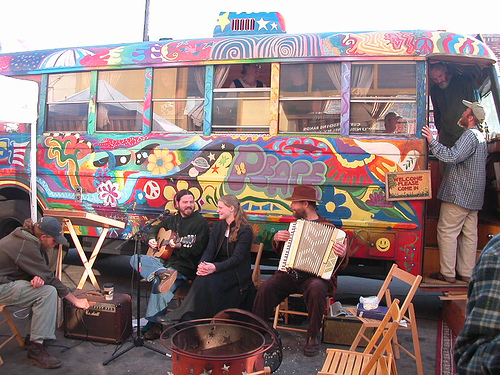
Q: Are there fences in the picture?
A: No, there are no fences.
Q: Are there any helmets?
A: No, there are no helmets.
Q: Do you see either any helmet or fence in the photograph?
A: No, there are no helmets or fences.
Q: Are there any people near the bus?
A: Yes, there is a person near the bus.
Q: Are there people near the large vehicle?
A: Yes, there is a person near the bus.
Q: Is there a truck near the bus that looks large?
A: No, there is a person near the bus.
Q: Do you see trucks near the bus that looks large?
A: No, there is a person near the bus.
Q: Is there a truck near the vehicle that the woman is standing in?
A: No, there is a person near the bus.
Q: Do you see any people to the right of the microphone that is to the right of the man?
A: Yes, there is a person to the right of the microphone.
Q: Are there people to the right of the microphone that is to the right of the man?
A: Yes, there is a person to the right of the microphone.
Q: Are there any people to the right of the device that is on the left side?
A: Yes, there is a person to the right of the microphone.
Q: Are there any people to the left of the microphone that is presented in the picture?
A: No, the person is to the right of the microphone.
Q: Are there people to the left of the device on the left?
A: No, the person is to the right of the microphone.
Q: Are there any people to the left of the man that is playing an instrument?
A: Yes, there is a person to the left of the man.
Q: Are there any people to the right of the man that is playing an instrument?
A: No, the person is to the left of the man.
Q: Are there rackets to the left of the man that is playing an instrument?
A: No, there is a person to the left of the man.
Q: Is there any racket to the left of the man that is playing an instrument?
A: No, there is a person to the left of the man.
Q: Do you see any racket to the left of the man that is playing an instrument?
A: No, there is a person to the left of the man.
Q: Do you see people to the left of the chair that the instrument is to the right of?
A: Yes, there is a person to the left of the chair.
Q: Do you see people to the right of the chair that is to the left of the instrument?
A: No, the person is to the left of the chair.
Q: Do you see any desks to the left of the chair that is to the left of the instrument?
A: No, there is a person to the left of the chair.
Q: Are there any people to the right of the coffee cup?
A: Yes, there is a person to the right of the coffee cup.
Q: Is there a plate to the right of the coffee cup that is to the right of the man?
A: No, there is a person to the right of the coffee cup.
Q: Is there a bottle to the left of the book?
A: No, there is a person to the left of the book.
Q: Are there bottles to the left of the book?
A: No, there is a person to the left of the book.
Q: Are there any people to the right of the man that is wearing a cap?
A: Yes, there is a person to the right of the man.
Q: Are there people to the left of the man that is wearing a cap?
A: No, the person is to the right of the man.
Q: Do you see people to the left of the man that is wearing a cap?
A: No, the person is to the right of the man.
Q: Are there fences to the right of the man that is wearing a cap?
A: No, there is a person to the right of the man.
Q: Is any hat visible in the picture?
A: Yes, there is a hat.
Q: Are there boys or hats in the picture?
A: Yes, there is a hat.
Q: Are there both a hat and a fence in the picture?
A: No, there is a hat but no fences.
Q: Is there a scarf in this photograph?
A: No, there are no scarves.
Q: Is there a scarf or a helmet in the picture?
A: No, there are no scarves or helmets.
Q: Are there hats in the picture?
A: Yes, there is a hat.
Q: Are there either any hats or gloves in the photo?
A: Yes, there is a hat.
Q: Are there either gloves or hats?
A: Yes, there is a hat.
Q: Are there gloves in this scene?
A: No, there are no gloves.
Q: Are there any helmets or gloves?
A: No, there are no gloves or helmets.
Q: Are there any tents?
A: No, there are no tents.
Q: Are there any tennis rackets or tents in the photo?
A: No, there are no tents or tennis rackets.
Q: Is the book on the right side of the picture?
A: Yes, the book is on the right of the image.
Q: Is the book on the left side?
A: No, the book is on the right of the image.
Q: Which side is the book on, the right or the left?
A: The book is on the right of the image.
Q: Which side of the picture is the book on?
A: The book is on the right of the image.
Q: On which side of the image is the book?
A: The book is on the right of the image.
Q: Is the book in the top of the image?
A: No, the book is in the bottom of the image.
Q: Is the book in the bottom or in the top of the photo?
A: The book is in the bottom of the image.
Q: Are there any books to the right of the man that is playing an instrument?
A: Yes, there is a book to the right of the man.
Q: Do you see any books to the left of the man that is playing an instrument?
A: No, the book is to the right of the man.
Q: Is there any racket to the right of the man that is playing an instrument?
A: No, there is a book to the right of the man.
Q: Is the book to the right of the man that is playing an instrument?
A: Yes, the book is to the right of the man.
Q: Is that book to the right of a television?
A: No, the book is to the right of the man.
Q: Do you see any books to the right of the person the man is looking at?
A: Yes, there is a book to the right of the person.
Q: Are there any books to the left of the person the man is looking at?
A: No, the book is to the right of the person.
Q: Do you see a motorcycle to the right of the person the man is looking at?
A: No, there is a book to the right of the person.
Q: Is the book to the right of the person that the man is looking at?
A: Yes, the book is to the right of the person.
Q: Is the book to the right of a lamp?
A: No, the book is to the right of the person.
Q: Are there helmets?
A: No, there are no helmets.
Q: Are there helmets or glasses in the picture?
A: No, there are no helmets or glasses.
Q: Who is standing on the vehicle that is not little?
A: The man is standing on the bus.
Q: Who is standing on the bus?
A: The man is standing on the bus.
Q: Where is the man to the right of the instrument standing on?
A: The man is standing on the bus.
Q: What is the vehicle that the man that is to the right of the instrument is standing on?
A: The vehicle is a bus.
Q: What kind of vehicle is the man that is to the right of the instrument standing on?
A: The man is standing on the bus.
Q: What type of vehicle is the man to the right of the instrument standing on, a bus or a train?
A: The man is standing on a bus.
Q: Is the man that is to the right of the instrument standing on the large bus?
A: Yes, the man is standing on the bus.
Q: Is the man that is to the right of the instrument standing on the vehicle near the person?
A: Yes, the man is standing on the bus.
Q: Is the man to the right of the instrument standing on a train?
A: No, the man is standing on the bus.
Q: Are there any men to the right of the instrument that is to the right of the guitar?
A: Yes, there is a man to the right of the instrument.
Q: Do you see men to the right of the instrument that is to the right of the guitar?
A: Yes, there is a man to the right of the instrument.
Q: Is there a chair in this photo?
A: Yes, there is a chair.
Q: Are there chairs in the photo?
A: Yes, there is a chair.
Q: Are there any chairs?
A: Yes, there is a chair.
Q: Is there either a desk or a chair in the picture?
A: Yes, there is a chair.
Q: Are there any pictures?
A: No, there are no pictures.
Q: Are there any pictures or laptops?
A: No, there are no pictures or laptops.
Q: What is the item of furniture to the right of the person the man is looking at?
A: The piece of furniture is a chair.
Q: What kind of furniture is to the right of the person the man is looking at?
A: The piece of furniture is a chair.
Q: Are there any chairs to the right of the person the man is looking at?
A: Yes, there is a chair to the right of the person.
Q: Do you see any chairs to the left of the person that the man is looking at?
A: No, the chair is to the right of the person.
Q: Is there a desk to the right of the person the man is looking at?
A: No, there is a chair to the right of the person.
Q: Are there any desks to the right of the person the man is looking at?
A: No, there is a chair to the right of the person.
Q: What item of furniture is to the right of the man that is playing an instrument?
A: The piece of furniture is a chair.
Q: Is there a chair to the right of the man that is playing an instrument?
A: Yes, there is a chair to the right of the man.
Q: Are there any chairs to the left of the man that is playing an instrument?
A: No, the chair is to the right of the man.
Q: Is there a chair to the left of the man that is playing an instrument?
A: No, the chair is to the right of the man.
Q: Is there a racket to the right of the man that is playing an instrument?
A: No, there is a chair to the right of the man.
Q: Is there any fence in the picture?
A: No, there are no fences.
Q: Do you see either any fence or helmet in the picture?
A: No, there are no fences or helmets.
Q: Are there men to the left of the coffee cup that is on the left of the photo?
A: Yes, there is a man to the left of the coffee cup.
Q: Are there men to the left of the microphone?
A: Yes, there is a man to the left of the microphone.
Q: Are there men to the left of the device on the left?
A: Yes, there is a man to the left of the microphone.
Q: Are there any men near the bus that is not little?
A: Yes, there is a man near the bus.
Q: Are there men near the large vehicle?
A: Yes, there is a man near the bus.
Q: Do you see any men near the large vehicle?
A: Yes, there is a man near the bus.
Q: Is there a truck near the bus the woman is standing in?
A: No, there is a man near the bus.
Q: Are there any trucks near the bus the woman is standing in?
A: No, there is a man near the bus.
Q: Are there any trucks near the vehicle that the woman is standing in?
A: No, there is a man near the bus.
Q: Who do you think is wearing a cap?
A: The man is wearing a cap.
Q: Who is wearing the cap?
A: The man is wearing a cap.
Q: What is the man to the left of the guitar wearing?
A: The man is wearing a cap.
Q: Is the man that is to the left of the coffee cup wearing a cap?
A: Yes, the man is wearing a cap.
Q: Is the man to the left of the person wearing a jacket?
A: No, the man is wearing a cap.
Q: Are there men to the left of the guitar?
A: Yes, there is a man to the left of the guitar.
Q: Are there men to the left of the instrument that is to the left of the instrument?
A: Yes, there is a man to the left of the guitar.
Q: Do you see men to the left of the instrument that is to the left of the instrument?
A: Yes, there is a man to the left of the guitar.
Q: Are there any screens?
A: No, there are no screens.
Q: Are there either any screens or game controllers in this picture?
A: No, there are no screens or game controllers.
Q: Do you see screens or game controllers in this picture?
A: No, there are no screens or game controllers.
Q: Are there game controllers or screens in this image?
A: No, there are no screens or game controllers.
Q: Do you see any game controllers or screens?
A: No, there are no screens or game controllers.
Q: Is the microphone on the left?
A: Yes, the microphone is on the left of the image.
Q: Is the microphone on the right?
A: No, the microphone is on the left of the image.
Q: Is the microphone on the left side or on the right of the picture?
A: The microphone is on the left of the image.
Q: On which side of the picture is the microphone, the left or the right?
A: The microphone is on the left of the image.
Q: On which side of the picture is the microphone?
A: The microphone is on the left of the image.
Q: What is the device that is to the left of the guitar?
A: The device is a microphone.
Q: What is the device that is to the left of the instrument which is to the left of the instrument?
A: The device is a microphone.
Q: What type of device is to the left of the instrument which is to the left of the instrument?
A: The device is a microphone.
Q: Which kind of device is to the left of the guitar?
A: The device is a microphone.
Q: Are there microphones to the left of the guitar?
A: Yes, there is a microphone to the left of the guitar.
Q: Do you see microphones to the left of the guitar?
A: Yes, there is a microphone to the left of the guitar.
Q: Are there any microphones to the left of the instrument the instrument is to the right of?
A: Yes, there is a microphone to the left of the guitar.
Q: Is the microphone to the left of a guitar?
A: Yes, the microphone is to the left of a guitar.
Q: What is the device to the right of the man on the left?
A: The device is a microphone.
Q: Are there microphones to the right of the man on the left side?
A: Yes, there is a microphone to the right of the man.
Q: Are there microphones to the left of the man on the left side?
A: No, the microphone is to the right of the man.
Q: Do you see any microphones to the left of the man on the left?
A: No, the microphone is to the right of the man.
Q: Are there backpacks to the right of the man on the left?
A: No, there is a microphone to the right of the man.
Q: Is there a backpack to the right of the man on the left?
A: No, there is a microphone to the right of the man.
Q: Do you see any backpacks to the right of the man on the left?
A: No, there is a microphone to the right of the man.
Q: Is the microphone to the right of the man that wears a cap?
A: Yes, the microphone is to the right of the man.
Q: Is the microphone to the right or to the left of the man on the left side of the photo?
A: The microphone is to the right of the man.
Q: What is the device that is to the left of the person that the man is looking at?
A: The device is a microphone.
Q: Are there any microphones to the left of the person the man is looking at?
A: Yes, there is a microphone to the left of the person.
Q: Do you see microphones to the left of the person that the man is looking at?
A: Yes, there is a microphone to the left of the person.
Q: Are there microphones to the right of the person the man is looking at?
A: No, the microphone is to the left of the person.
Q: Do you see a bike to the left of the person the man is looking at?
A: No, there is a microphone to the left of the person.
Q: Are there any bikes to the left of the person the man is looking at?
A: No, there is a microphone to the left of the person.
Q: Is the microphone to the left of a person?
A: Yes, the microphone is to the left of a person.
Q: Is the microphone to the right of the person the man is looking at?
A: No, the microphone is to the left of the person.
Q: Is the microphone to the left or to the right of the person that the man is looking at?
A: The microphone is to the left of the person.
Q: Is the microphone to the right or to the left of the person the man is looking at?
A: The microphone is to the left of the person.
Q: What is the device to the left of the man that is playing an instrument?
A: The device is a microphone.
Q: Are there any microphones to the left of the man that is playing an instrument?
A: Yes, there is a microphone to the left of the man.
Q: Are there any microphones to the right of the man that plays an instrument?
A: No, the microphone is to the left of the man.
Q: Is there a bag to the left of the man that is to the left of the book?
A: No, there is a microphone to the left of the man.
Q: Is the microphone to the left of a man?
A: Yes, the microphone is to the left of a man.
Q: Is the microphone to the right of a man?
A: No, the microphone is to the left of a man.